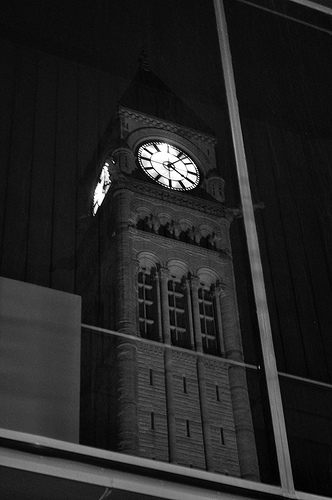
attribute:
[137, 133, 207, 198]
clock — white, shining, lit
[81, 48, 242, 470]
tower — building, tall, stone, pointed, decorated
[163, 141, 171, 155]
number — black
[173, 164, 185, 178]
hand — black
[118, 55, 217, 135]
roof — black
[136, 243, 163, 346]
window — large, arched, tall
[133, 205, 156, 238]
arch — divided, small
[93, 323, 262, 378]
bar — horizontal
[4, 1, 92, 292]
wall — slit